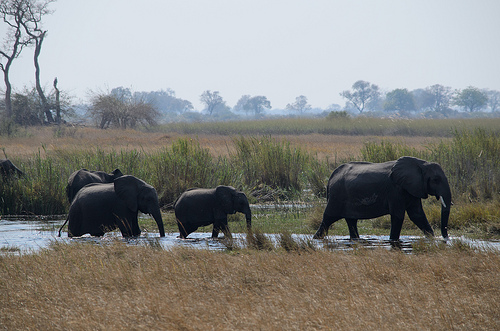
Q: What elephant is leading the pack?
A: The largest elephant.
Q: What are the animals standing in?
A: Water.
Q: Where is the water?
A: By the grass.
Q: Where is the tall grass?
A: Behind the elephants.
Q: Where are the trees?
A: Behind the field.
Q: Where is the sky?
A: Above the field.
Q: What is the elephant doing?
A: Walking.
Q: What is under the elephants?
A: Water.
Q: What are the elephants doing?
A: Walking in water.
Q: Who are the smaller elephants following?
A: Large elephant.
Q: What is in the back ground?
A: Bunch of trees.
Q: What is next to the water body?
A: Tall grass.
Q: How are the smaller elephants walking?
A: In a pack.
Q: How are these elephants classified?
A: Wild.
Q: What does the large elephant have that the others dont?
A: Tusks.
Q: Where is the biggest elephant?
A: In the front.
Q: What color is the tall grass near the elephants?
A: Green.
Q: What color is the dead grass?
A: Brown.